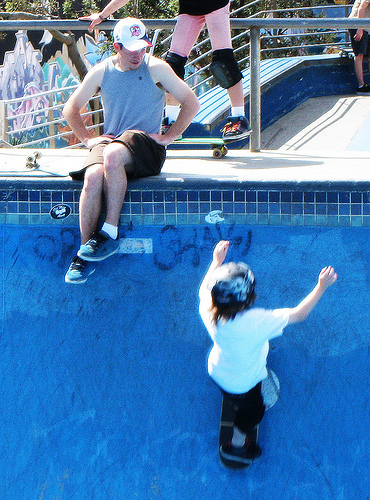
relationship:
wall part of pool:
[4, 251, 197, 384] [0, 181, 370, 500]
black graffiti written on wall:
[150, 219, 260, 266] [3, 187, 367, 498]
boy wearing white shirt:
[192, 235, 336, 457] [192, 283, 294, 394]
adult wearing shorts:
[62, 17, 200, 285] [89, 130, 199, 179]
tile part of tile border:
[229, 188, 370, 227] [0, 181, 370, 225]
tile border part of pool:
[0, 181, 370, 225] [0, 181, 370, 500]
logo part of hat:
[126, 25, 143, 36] [113, 15, 154, 54]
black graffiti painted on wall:
[153, 220, 252, 271] [3, 187, 367, 498]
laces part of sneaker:
[69, 256, 85, 271] [57, 232, 138, 293]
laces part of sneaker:
[85, 229, 108, 249] [76, 229, 121, 262]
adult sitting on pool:
[62, 17, 200, 285] [5, 177, 367, 498]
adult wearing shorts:
[62, 17, 200, 285] [66, 128, 168, 182]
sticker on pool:
[46, 200, 76, 224] [5, 177, 367, 498]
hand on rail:
[76, 13, 108, 37] [13, 13, 363, 43]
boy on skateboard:
[199, 239, 338, 469] [215, 394, 252, 473]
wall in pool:
[38, 90, 368, 279] [5, 177, 367, 498]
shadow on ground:
[239, 144, 322, 175] [5, 144, 368, 183]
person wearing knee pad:
[164, 0, 253, 159] [208, 48, 243, 89]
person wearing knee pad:
[164, 0, 253, 159] [165, 51, 187, 81]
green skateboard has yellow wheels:
[161, 133, 247, 158] [212, 144, 228, 157]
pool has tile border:
[5, 192, 339, 473] [0, 181, 370, 225]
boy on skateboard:
[199, 239, 338, 469] [218, 392, 259, 471]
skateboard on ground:
[0, 151, 42, 173] [0, 146, 90, 180]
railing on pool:
[0, 18, 370, 151] [5, 177, 367, 498]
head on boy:
[211, 261, 255, 316] [199, 239, 338, 469]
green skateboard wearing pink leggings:
[171, 130, 253, 159] [171, 8, 246, 71]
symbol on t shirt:
[137, 75, 142, 82] [99, 52, 167, 134]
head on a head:
[211, 261, 255, 316] [205, 263, 258, 318]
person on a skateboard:
[168, 2, 266, 125] [217, 382, 263, 471]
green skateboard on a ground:
[171, 130, 253, 159] [0, 144, 370, 180]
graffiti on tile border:
[31, 220, 252, 269] [0, 181, 370, 225]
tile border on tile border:
[2, 186, 369, 226] [0, 181, 370, 225]